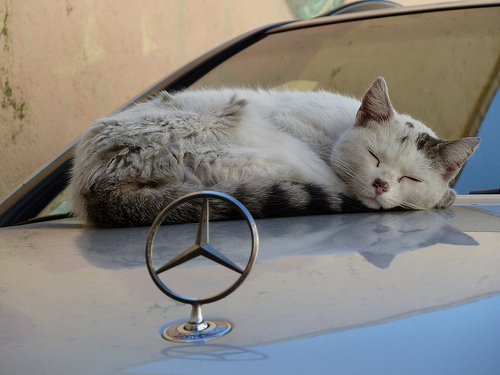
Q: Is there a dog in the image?
A: No, there are no dogs.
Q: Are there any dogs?
A: No, there are no dogs.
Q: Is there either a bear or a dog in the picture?
A: No, there are no dogs or bears.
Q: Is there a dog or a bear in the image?
A: No, there are no dogs or bears.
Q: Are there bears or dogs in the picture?
A: No, there are no dogs or bears.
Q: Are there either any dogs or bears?
A: No, there are no dogs or bears.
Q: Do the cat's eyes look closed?
A: Yes, the eyes are closed.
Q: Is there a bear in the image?
A: No, there are no bears.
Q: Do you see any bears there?
A: No, there are no bears.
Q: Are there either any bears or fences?
A: No, there are no bears or fences.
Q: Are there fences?
A: No, there are no fences.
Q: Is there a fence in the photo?
A: No, there are no fences.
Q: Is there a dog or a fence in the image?
A: No, there are no fences or dogs.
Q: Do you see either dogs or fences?
A: No, there are no fences or dogs.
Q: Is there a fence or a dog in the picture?
A: No, there are no fences or dogs.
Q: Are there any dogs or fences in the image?
A: No, there are no fences or dogs.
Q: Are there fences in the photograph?
A: No, there are no fences.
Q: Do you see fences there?
A: No, there are no fences.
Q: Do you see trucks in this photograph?
A: No, there are no trucks.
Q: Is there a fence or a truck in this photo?
A: No, there are no trucks or fences.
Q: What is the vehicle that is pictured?
A: The vehicle is a car.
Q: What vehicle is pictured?
A: The vehicle is a car.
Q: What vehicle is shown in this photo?
A: The vehicle is a car.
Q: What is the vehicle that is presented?
A: The vehicle is a car.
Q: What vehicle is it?
A: The vehicle is a car.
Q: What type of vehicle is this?
A: This is a car.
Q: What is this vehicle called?
A: This is a car.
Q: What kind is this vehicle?
A: This is a car.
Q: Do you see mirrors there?
A: No, there are no mirrors.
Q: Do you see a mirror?
A: No, there are no mirrors.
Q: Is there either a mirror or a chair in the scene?
A: No, there are no mirrors or chairs.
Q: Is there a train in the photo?
A: No, there are no trains.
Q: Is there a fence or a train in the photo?
A: No, there are no trains or fences.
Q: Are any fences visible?
A: No, there are no fences.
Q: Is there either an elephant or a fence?
A: No, there are no fences or elephants.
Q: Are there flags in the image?
A: No, there are no flags.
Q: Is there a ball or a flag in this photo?
A: No, there are no flags or balls.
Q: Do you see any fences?
A: No, there are no fences.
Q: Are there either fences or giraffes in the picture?
A: No, there are no fences or giraffes.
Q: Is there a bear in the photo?
A: No, there are no bears.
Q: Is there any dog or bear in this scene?
A: No, there are no bears or dogs.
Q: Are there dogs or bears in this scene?
A: No, there are no bears or dogs.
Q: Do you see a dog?
A: No, there are no dogs.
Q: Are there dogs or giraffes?
A: No, there are no dogs or giraffes.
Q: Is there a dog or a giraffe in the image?
A: No, there are no dogs or giraffes.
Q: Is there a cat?
A: Yes, there is a cat.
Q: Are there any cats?
A: Yes, there is a cat.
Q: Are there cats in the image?
A: Yes, there is a cat.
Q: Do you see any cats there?
A: Yes, there is a cat.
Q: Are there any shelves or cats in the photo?
A: Yes, there is a cat.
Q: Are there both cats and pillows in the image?
A: No, there is a cat but no pillows.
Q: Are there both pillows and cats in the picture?
A: No, there is a cat but no pillows.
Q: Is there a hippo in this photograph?
A: No, there are no hippoes.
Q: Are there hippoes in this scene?
A: No, there are no hippoes.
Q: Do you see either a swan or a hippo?
A: No, there are no hippoes or swans.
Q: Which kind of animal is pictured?
A: The animal is a cat.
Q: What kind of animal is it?
A: The animal is a cat.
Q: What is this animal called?
A: This is a cat.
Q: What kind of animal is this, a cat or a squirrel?
A: This is a cat.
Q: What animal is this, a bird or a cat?
A: This is a cat.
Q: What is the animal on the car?
A: The animal is a cat.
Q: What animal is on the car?
A: The animal is a cat.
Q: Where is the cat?
A: The cat is on the car.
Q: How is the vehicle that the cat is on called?
A: The vehicle is a car.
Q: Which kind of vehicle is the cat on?
A: The cat is on the car.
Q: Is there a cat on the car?
A: Yes, there is a cat on the car.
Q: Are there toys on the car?
A: No, there is a cat on the car.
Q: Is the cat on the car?
A: Yes, the cat is on the car.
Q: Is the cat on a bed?
A: No, the cat is on the car.